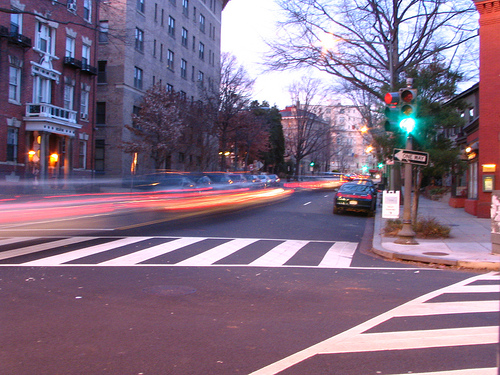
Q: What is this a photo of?
A: A street corner.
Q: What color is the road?
A: Black.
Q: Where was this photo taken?
A: In a city.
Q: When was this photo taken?
A: In the daytime.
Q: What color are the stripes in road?
A: White.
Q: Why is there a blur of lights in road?
A: Cars are moving.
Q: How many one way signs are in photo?
A: One.